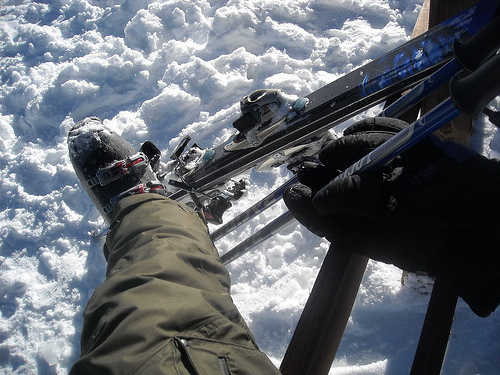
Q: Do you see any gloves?
A: Yes, there are gloves.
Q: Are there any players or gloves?
A: Yes, there are gloves.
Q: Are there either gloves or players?
A: Yes, there are gloves.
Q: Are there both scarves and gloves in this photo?
A: No, there are gloves but no scarves.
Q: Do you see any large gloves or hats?
A: Yes, there are large gloves.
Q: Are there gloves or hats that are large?
A: Yes, the gloves are large.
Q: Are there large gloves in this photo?
A: Yes, there are large gloves.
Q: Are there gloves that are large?
A: Yes, there are gloves that are large.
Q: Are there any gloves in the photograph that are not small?
A: Yes, there are large gloves.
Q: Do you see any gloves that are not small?
A: Yes, there are large gloves.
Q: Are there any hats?
A: No, there are no hats.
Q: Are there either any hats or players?
A: No, there are no hats or players.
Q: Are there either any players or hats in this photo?
A: No, there are no hats or players.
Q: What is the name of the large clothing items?
A: The clothing items are gloves.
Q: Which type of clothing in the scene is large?
A: The clothing is gloves.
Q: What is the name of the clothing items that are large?
A: The clothing items are gloves.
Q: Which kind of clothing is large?
A: The clothing is gloves.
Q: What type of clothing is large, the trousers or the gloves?
A: The gloves are large.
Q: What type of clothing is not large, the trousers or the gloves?
A: The trousers are not large.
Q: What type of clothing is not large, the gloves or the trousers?
A: The trousers are not large.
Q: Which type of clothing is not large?
A: The clothing is pants.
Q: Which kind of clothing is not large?
A: The clothing is pants.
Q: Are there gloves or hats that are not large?
A: No, there are gloves but they are large.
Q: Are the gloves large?
A: Yes, the gloves are large.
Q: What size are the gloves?
A: The gloves are large.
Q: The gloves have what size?
A: The gloves are large.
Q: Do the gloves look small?
A: No, the gloves are large.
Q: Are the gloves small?
A: No, the gloves are large.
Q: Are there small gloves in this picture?
A: No, there are gloves but they are large.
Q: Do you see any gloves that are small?
A: No, there are gloves but they are large.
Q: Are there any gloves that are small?
A: No, there are gloves but they are large.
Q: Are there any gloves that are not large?
A: No, there are gloves but they are large.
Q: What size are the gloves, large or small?
A: The gloves are large.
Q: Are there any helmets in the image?
A: No, there are no helmets.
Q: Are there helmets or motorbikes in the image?
A: No, there are no helmets or motorbikes.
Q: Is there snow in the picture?
A: Yes, there is snow.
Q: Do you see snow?
A: Yes, there is snow.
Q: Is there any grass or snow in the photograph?
A: Yes, there is snow.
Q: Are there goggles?
A: No, there are no goggles.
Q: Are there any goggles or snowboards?
A: No, there are no goggles or snowboards.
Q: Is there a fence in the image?
A: No, there are no fences.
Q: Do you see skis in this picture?
A: Yes, there are skis.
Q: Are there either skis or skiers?
A: Yes, there are skis.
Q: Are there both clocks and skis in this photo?
A: No, there are skis but no clocks.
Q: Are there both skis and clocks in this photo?
A: No, there are skis but no clocks.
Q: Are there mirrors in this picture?
A: No, there are no mirrors.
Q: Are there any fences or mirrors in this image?
A: No, there are no mirrors or fences.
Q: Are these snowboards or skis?
A: These are skis.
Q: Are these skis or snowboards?
A: These are skis.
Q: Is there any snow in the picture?
A: Yes, there is snow.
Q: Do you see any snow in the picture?
A: Yes, there is snow.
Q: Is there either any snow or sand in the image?
A: Yes, there is snow.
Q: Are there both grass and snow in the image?
A: No, there is snow but no grass.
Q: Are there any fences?
A: No, there are no fences.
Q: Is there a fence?
A: No, there are no fences.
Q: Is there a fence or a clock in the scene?
A: No, there are no fences or clocks.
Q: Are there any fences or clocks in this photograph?
A: No, there are no fences or clocks.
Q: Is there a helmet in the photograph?
A: No, there are no helmets.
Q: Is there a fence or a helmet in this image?
A: No, there are no helmets or fences.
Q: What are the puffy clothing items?
A: The clothing items are pants.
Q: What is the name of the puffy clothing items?
A: The clothing items are pants.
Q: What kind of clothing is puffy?
A: The clothing is pants.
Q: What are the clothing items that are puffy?
A: The clothing items are pants.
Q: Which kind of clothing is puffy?
A: The clothing is pants.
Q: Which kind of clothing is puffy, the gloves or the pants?
A: The pants are puffy.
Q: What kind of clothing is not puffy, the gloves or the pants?
A: The gloves are not puffy.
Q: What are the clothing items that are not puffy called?
A: The clothing items are gloves.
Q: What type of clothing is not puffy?
A: The clothing is gloves.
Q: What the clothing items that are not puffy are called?
A: The clothing items are gloves.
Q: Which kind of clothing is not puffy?
A: The clothing is gloves.